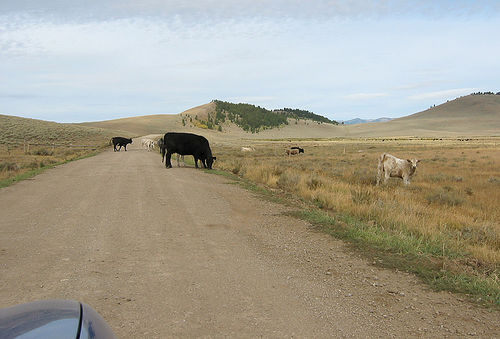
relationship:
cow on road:
[163, 132, 216, 169] [0, 133, 499, 338]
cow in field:
[241, 147, 257, 152] [152, 135, 499, 309]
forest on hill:
[180, 99, 344, 134] [181, 99, 290, 133]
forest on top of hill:
[180, 99, 344, 134] [181, 99, 290, 133]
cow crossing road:
[111, 137, 133, 152] [0, 133, 499, 338]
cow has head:
[163, 132, 216, 169] [205, 156, 216, 169]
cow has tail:
[163, 132, 216, 169] [162, 136, 166, 164]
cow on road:
[111, 137, 133, 152] [0, 133, 499, 338]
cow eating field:
[163, 132, 216, 169] [152, 135, 499, 309]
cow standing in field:
[378, 153, 422, 185] [152, 135, 499, 309]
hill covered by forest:
[181, 99, 290, 133] [180, 99, 344, 134]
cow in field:
[378, 153, 422, 185] [152, 135, 499, 309]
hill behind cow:
[181, 99, 290, 133] [163, 132, 216, 169]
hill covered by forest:
[432, 93, 500, 116] [431, 92, 500, 108]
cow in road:
[163, 132, 216, 169] [0, 133, 499, 338]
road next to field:
[0, 133, 499, 338] [152, 135, 499, 309]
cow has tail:
[378, 153, 422, 185] [380, 154, 386, 181]